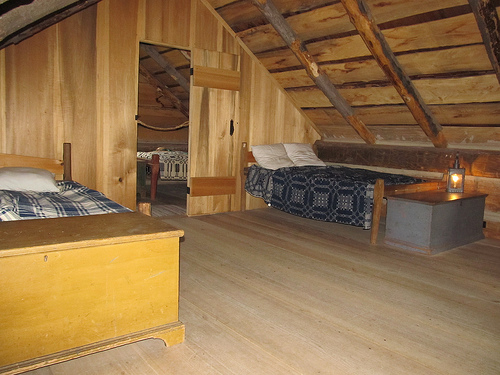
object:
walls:
[2, 2, 322, 218]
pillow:
[250, 143, 297, 171]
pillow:
[283, 142, 325, 166]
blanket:
[247, 163, 425, 230]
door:
[187, 47, 248, 221]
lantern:
[436, 155, 467, 194]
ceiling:
[205, 1, 500, 150]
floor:
[3, 208, 500, 373]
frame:
[241, 140, 451, 246]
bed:
[235, 138, 453, 246]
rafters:
[208, 2, 498, 151]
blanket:
[1, 180, 134, 223]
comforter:
[245, 165, 427, 231]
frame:
[0, 144, 71, 184]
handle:
[229, 120, 236, 136]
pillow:
[1, 167, 58, 194]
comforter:
[1, 176, 132, 221]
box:
[383, 189, 488, 258]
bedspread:
[2, 179, 134, 227]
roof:
[206, 2, 499, 149]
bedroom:
[2, 1, 500, 374]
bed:
[0, 137, 135, 226]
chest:
[0, 211, 188, 375]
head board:
[0, 141, 72, 185]